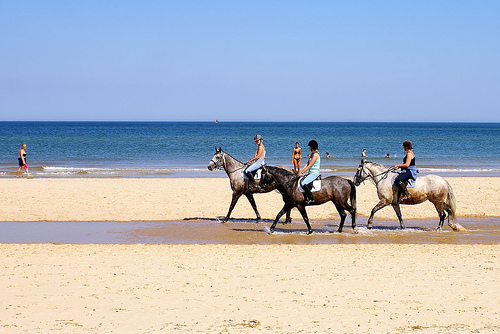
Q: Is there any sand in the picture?
A: Yes, there is sand.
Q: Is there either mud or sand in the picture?
A: Yes, there is sand.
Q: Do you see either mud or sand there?
A: Yes, there is sand.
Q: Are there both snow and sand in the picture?
A: No, there is sand but no snow.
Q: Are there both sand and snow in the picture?
A: No, there is sand but no snow.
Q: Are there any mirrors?
A: No, there are no mirrors.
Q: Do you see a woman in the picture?
A: Yes, there is a woman.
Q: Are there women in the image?
A: Yes, there is a woman.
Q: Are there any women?
A: Yes, there is a woman.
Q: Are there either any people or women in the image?
A: Yes, there is a woman.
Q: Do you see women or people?
A: Yes, there is a woman.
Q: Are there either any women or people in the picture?
A: Yes, there is a woman.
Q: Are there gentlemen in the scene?
A: No, there are no gentlemen.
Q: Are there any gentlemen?
A: No, there are no gentlemen.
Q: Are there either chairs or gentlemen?
A: No, there are no gentlemen or chairs.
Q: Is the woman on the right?
A: Yes, the woman is on the right of the image.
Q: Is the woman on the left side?
A: No, the woman is on the right of the image.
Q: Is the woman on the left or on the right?
A: The woman is on the right of the image.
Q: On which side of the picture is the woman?
A: The woman is on the right of the image.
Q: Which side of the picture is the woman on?
A: The woman is on the right of the image.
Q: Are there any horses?
A: Yes, there is a horse.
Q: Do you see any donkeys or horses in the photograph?
A: Yes, there is a horse.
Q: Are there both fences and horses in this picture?
A: No, there is a horse but no fences.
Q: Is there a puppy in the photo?
A: No, there are no puppys.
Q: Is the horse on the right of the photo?
A: Yes, the horse is on the right of the image.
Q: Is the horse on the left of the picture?
A: No, the horse is on the right of the image.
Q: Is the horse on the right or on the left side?
A: The horse is on the right of the image.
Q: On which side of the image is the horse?
A: The horse is on the right of the image.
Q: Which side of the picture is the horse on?
A: The horse is on the right of the image.